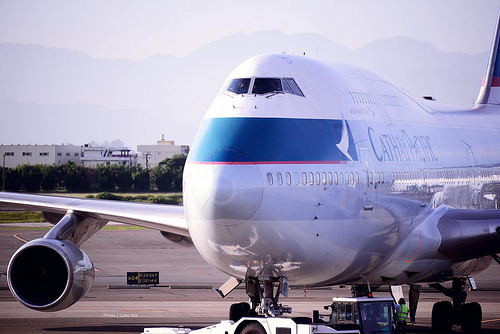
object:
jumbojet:
[0, 22, 500, 334]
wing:
[0, 191, 190, 237]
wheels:
[431, 301, 453, 332]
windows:
[252, 78, 283, 94]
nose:
[191, 149, 264, 226]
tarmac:
[0, 316, 215, 333]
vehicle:
[324, 297, 394, 333]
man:
[394, 298, 409, 332]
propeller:
[10, 245, 71, 305]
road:
[0, 222, 500, 333]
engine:
[9, 237, 94, 312]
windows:
[341, 92, 348, 103]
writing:
[367, 127, 438, 161]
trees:
[22, 163, 42, 191]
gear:
[229, 277, 292, 316]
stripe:
[192, 161, 345, 164]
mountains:
[2, 40, 141, 62]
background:
[0, 1, 500, 149]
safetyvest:
[396, 304, 407, 320]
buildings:
[1, 143, 82, 167]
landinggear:
[432, 301, 483, 331]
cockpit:
[222, 77, 306, 98]